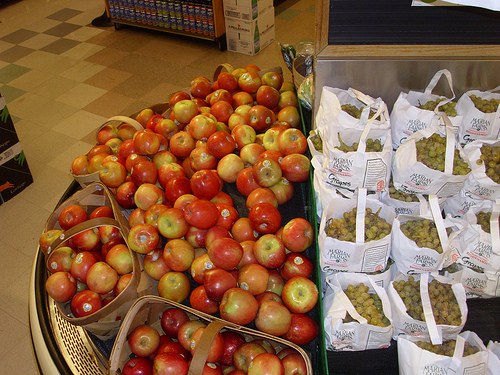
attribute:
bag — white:
[396, 330, 488, 373]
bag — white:
[321, 271, 393, 351]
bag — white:
[388, 271, 469, 340]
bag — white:
[317, 188, 395, 273]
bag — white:
[389, 193, 461, 275]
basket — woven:
[40, 184, 157, 339]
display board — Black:
[325, 0, 499, 42]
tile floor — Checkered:
[30, 27, 120, 104]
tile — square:
[1, 0, 315, 374]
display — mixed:
[32, 61, 498, 372]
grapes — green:
[425, 141, 442, 168]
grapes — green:
[407, 220, 434, 244]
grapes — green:
[331, 210, 385, 237]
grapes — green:
[338, 142, 378, 152]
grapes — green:
[410, 94, 454, 109]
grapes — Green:
[322, 204, 396, 248]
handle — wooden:
[41, 217, 121, 273]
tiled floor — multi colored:
[2, 6, 196, 265]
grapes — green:
[335, 210, 385, 245]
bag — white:
[324, 193, 398, 257]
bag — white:
[322, 272, 395, 342]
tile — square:
[96, 63, 119, 90]